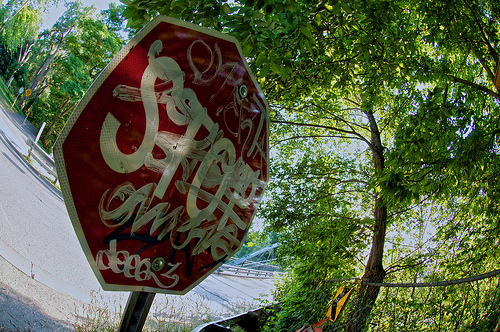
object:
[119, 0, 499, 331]
tree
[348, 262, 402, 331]
trunk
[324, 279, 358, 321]
sign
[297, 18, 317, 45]
leaves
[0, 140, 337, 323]
road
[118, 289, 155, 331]
pole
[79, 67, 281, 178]
sign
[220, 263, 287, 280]
bridge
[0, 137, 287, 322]
path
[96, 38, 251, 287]
graffiti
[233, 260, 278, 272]
guard rail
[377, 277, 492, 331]
fence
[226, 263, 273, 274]
river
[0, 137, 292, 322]
street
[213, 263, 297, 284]
railing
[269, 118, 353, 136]
branch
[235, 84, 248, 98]
tags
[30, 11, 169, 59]
day